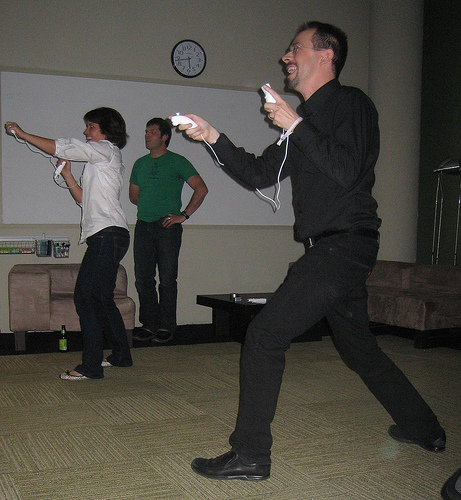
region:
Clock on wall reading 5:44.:
[164, 34, 211, 80]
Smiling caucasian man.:
[269, 10, 351, 92]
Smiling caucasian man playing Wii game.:
[166, 0, 386, 221]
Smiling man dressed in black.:
[186, 12, 443, 484]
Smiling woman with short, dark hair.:
[75, 93, 133, 145]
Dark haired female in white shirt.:
[6, 98, 133, 229]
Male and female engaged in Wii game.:
[0, 14, 451, 483]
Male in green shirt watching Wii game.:
[12, 20, 450, 353]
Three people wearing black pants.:
[3, 15, 458, 458]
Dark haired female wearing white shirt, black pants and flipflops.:
[4, 101, 135, 390]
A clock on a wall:
[169, 40, 207, 79]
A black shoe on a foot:
[190, 448, 269, 480]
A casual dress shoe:
[58, 366, 101, 380]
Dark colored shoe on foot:
[389, 422, 444, 452]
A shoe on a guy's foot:
[152, 327, 172, 343]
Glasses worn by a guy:
[287, 43, 333, 56]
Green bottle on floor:
[57, 324, 68, 352]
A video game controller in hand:
[169, 112, 197, 131]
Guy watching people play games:
[129, 116, 207, 344]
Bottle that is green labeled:
[57, 324, 67, 351]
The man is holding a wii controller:
[168, 104, 257, 184]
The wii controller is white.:
[167, 100, 229, 175]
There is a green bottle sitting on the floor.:
[29, 316, 71, 357]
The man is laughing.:
[273, 14, 345, 107]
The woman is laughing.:
[66, 100, 136, 161]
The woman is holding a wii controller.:
[6, 110, 127, 187]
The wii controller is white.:
[2, 120, 87, 191]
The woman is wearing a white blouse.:
[42, 126, 136, 253]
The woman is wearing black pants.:
[63, 221, 138, 379]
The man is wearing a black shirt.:
[195, 87, 389, 243]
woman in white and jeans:
[3, 105, 130, 382]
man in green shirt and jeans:
[127, 117, 211, 341]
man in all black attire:
[169, 17, 444, 483]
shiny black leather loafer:
[189, 452, 269, 481]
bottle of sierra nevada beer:
[54, 324, 69, 351]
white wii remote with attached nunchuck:
[167, 83, 305, 212]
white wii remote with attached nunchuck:
[2, 120, 80, 191]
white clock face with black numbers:
[169, 37, 207, 77]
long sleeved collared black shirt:
[203, 77, 380, 237]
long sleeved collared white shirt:
[53, 135, 130, 243]